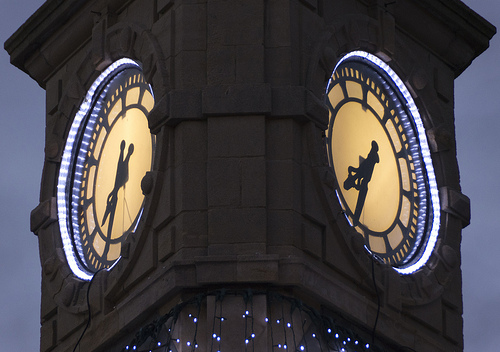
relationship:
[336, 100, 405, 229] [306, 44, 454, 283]
face on clock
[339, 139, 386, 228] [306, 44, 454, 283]
hands on clock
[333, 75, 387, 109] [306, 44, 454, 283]
marks on clock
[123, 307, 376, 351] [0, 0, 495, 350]
lights on tower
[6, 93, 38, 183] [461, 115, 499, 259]
clouds in sky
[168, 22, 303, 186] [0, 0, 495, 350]
brick on tower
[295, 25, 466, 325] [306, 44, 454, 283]
frame of clock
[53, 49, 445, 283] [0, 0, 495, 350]
clocks on tower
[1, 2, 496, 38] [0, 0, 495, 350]
top of tower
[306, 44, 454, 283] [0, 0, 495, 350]
clock on tower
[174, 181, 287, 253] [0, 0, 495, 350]
stone on tower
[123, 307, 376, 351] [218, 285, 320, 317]
lights are on strings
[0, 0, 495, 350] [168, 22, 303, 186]
tower made of brick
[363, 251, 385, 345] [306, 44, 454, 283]
wire by clock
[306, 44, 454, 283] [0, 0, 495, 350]
clock on a tower